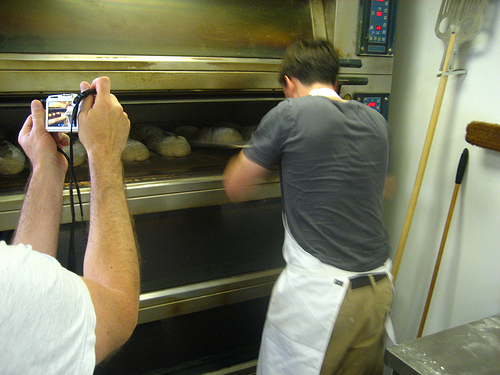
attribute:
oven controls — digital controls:
[356, 0, 394, 56]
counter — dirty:
[389, 317, 497, 367]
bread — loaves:
[130, 120, 249, 159]